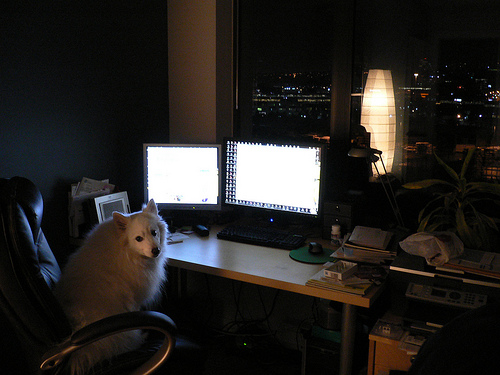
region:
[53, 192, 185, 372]
Dog on the chair.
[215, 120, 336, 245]
Monitor on the desk.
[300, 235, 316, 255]
Mouse on the desk.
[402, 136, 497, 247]
Plant beside the desk.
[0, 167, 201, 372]
Chair by the desk.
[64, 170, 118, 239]
Papers by the wall.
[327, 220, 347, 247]
Bottle on the desk.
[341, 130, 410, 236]
Light on the desk.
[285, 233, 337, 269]
Green mouse pad under the mouse.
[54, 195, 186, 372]
white coloring on the dog.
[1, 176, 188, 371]
white dog on chair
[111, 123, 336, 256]
two screen on desk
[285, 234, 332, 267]
mouse is color black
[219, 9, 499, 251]
window behind computer screen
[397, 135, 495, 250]
a plant in a pot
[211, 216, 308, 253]
the keyboard is black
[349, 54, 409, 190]
a lamp reflected on the window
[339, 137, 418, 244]
a lamp on table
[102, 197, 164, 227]
dog has pointy ears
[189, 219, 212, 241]
mouse is color black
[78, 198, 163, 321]
dog in desk chair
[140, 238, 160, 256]
nose of the dog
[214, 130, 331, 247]
computer on the desk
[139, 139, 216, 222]
computer on the desk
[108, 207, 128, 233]
ear of the dog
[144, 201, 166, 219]
ear of the dog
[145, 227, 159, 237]
eye of the dog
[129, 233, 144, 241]
eye of the dog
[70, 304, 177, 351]
arm of the chair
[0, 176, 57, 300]
back of the chair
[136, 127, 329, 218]
Two monitors on the desk.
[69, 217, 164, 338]
The dog is sitting on the chair.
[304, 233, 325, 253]
Mouse on the desk.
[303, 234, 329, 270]
Mouse on the green mousepad.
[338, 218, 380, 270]
Stack of papers in the corner of desk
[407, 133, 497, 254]
Plant next to the desk.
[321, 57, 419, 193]
A reflection of the light in the window.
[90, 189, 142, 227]
A frame on the desk.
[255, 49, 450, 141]
Lights on the building outside of the window.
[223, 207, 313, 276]
The keyboard on the desk.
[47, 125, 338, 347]
A white dog sitting on a chair in front of two computer monitors.